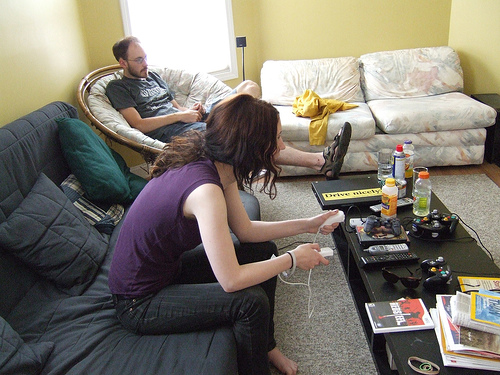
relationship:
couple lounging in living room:
[67, 28, 356, 368] [1, 36, 485, 373]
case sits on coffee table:
[311, 176, 365, 205] [325, 180, 485, 373]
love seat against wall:
[253, 44, 497, 179] [79, 0, 450, 162]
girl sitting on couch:
[109, 93, 338, 375] [3, 97, 261, 372]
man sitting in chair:
[107, 36, 351, 178] [78, 65, 234, 164]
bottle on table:
[411, 171, 431, 218] [321, 178, 481, 358]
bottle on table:
[380, 178, 399, 220] [321, 178, 481, 358]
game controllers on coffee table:
[410, 208, 461, 240] [325, 180, 485, 373]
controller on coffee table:
[420, 256, 453, 290] [325, 180, 485, 373]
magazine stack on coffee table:
[423, 288, 498, 373] [432, 244, 489, 273]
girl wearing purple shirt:
[109, 93, 338, 375] [95, 162, 336, 275]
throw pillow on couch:
[6, 177, 110, 294] [3, 97, 261, 372]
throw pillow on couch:
[59, 114, 153, 198] [3, 97, 261, 372]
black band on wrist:
[286, 248, 293, 268] [283, 247, 307, 270]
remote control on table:
[362, 240, 447, 276] [313, 159, 468, 371]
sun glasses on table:
[376, 262, 426, 290] [305, 167, 494, 373]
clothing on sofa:
[292, 88, 360, 146] [260, 45, 498, 177]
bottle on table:
[380, 178, 399, 220] [318, 160, 484, 374]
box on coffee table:
[364, 298, 434, 335] [332, 170, 499, 373]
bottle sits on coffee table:
[411, 171, 431, 218] [325, 180, 485, 373]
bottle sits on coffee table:
[378, 175, 398, 220] [325, 180, 485, 373]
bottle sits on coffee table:
[411, 166, 432, 217] [325, 180, 485, 373]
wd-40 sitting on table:
[388, 142, 408, 186] [318, 160, 484, 374]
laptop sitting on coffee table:
[310, 173, 384, 208] [325, 180, 485, 373]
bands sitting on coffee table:
[392, 331, 443, 373] [329, 183, 499, 373]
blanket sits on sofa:
[292, 87, 361, 148] [229, 48, 494, 176]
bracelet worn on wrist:
[281, 249, 297, 278] [281, 247, 304, 274]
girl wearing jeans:
[109, 93, 338, 375] [103, 236, 278, 373]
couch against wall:
[0, 113, 207, 360] [0, 0, 107, 149]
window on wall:
[121, 0, 241, 91] [79, 0, 450, 162]